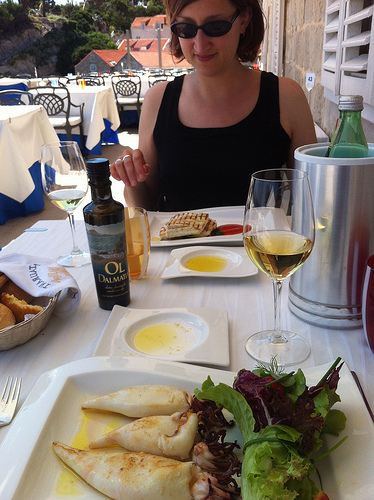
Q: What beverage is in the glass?
A: Wine.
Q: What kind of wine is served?
A: White.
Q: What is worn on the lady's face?
A: Sunglasses.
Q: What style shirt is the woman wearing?
A: Tank top.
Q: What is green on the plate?
A: Salad.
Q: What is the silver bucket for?
A: Chilling wine.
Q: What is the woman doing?
A: Eating.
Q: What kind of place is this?
A: Restaurant.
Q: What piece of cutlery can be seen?
A: Fork.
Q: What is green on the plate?
A: Salad.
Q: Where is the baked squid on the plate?
A: Next to the salad.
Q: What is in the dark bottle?
A: Olive oil.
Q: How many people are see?
A: One.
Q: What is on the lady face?
A: Shades.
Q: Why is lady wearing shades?
A: Sunny.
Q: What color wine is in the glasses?
A: White.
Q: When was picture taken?
A: Daytime.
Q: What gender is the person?
A: Female.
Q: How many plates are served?
A: Two.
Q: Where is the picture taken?
A: At a cafe.